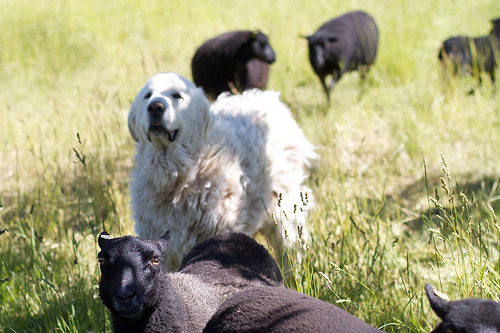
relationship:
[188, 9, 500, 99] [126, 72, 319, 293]
three sheep behind dog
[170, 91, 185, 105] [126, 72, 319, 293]
eye of dog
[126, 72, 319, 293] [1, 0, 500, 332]
dog in grass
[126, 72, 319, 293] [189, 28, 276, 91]
dog with sheep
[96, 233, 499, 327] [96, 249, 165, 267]
sheep has brown eyes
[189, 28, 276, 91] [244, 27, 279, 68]
sheep turned its head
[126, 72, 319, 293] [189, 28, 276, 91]
dog and sheep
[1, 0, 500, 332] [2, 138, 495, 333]
grass has taller blades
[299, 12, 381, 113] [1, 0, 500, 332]
sheep in grass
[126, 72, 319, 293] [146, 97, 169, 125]
dog has a black nose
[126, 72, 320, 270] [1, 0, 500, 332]
dog in grass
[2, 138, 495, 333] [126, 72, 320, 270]
taller blades amid dog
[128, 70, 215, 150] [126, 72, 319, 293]
head of dog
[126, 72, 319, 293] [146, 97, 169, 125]
dog lifts h nose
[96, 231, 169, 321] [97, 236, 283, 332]
head of a sheep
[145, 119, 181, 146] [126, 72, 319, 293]
mouth of dog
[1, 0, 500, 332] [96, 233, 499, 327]
grass with sheep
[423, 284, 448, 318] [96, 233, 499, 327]
ear on a sheep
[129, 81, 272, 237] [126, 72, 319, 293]
shadow on dog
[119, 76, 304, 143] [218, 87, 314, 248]
back has sunlight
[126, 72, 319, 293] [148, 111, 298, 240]
dog has hair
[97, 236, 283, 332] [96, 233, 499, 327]
sheep next to sheep